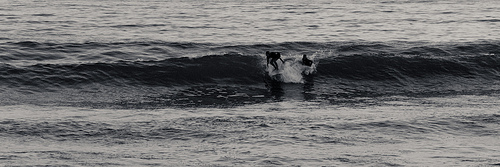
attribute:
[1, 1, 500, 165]
water — rippled, dark, calm, blue, wavy, swift, strong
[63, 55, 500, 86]
wave — smooth, medium, white, small, breaking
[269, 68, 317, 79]
surfboards — pointed, white, breaking